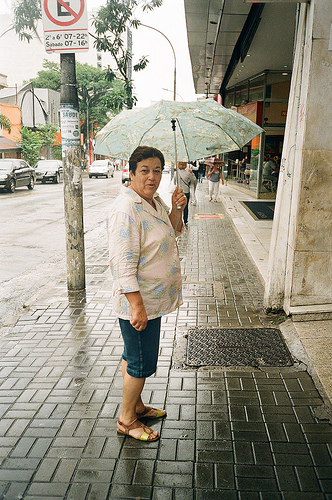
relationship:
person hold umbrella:
[105, 145, 188, 443] [85, 93, 268, 169]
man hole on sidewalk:
[181, 323, 298, 371] [26, 197, 302, 498]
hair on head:
[128, 145, 165, 174] [128, 146, 165, 197]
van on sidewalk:
[88, 159, 115, 179] [0, 171, 332, 500]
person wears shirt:
[105, 145, 188, 443] [106, 199, 183, 288]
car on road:
[0, 155, 38, 196] [4, 174, 110, 271]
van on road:
[84, 155, 120, 183] [0, 160, 133, 290]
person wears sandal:
[105, 145, 186, 440] [135, 406, 166, 418]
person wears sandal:
[105, 145, 186, 440] [117, 419, 160, 442]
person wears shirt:
[105, 145, 188, 443] [91, 187, 217, 324]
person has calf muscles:
[105, 145, 188, 443] [115, 363, 140, 400]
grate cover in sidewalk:
[186, 310, 298, 378] [24, 195, 279, 467]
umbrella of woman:
[82, 97, 280, 156] [91, 127, 197, 350]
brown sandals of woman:
[106, 397, 174, 447] [105, 150, 191, 450]